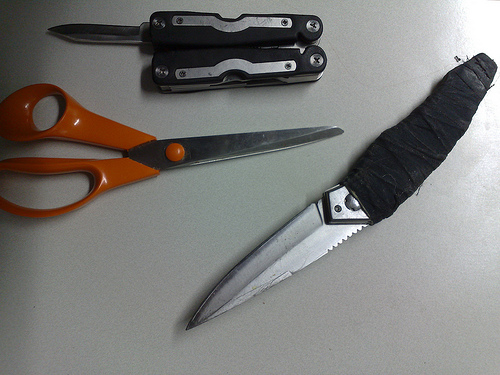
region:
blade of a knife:
[171, 182, 372, 333]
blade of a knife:
[37, 15, 150, 47]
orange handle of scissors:
[0, 146, 154, 220]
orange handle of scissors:
[0, 75, 162, 152]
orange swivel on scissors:
[165, 141, 184, 161]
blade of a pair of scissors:
[126, 120, 353, 180]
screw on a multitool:
[305, 50, 325, 66]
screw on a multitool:
[305, 16, 322, 32]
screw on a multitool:
[152, 63, 171, 80]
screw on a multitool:
[150, 14, 168, 32]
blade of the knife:
[187, 195, 342, 332]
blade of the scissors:
[226, 115, 346, 168]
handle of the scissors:
[0, 167, 112, 220]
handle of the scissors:
[14, 80, 127, 139]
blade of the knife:
[44, 5, 134, 52]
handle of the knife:
[347, 42, 467, 216]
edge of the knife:
[328, 239, 345, 254]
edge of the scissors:
[246, 140, 309, 172]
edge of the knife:
[71, 32, 105, 54]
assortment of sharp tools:
[5, 0, 478, 373]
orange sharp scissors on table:
[0, 66, 357, 241]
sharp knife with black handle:
[139, 57, 493, 343]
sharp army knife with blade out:
[37, 6, 379, 107]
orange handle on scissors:
[0, 75, 167, 245]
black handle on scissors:
[347, 48, 492, 256]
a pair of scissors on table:
[1, 58, 356, 238]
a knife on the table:
[184, 49, 489, 352]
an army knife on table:
[36, 4, 353, 79]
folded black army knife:
[137, 43, 338, 92]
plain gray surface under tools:
[5, 4, 496, 369]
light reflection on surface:
[467, 2, 497, 113]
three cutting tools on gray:
[4, 8, 493, 332]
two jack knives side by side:
[47, 10, 324, 92]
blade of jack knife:
[45, 19, 147, 42]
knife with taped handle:
[184, 54, 494, 330]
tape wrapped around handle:
[340, 54, 494, 224]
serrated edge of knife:
[326, 224, 366, 254]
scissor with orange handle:
[4, 82, 342, 221]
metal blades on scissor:
[127, 123, 346, 174]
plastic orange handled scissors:
[7, 77, 346, 221]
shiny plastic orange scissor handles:
[4, 81, 184, 226]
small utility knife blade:
[40, 13, 147, 53]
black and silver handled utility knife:
[142, 4, 329, 91]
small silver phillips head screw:
[301, 17, 322, 34]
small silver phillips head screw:
[306, 48, 326, 70]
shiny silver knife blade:
[169, 180, 370, 332]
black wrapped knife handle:
[336, 48, 498, 229]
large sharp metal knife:
[182, 49, 496, 342]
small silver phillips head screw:
[150, 60, 172, 80]